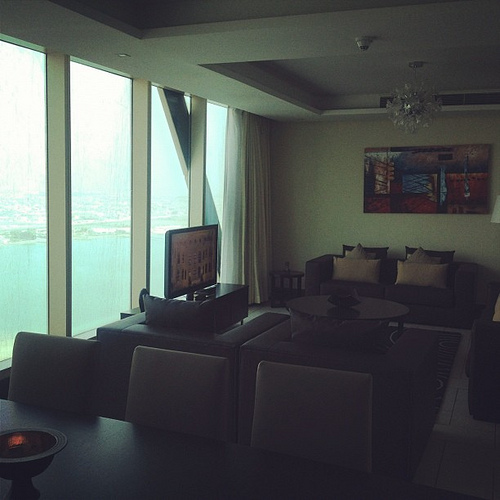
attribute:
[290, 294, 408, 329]
table — centered, round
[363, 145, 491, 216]
picture — hanging, large, colorful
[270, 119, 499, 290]
wall — yellow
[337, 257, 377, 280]
pillow — long, decorative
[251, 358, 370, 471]
chair — leather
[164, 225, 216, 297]
screen — facing, flat, black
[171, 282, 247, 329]
table — small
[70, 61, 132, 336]
window — long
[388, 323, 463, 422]
rug — centered, white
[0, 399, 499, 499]
table — partial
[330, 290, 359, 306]
bowl — round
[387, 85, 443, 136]
light — hanging, dangling, glass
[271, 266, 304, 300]
table — round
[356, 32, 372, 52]
camera — white